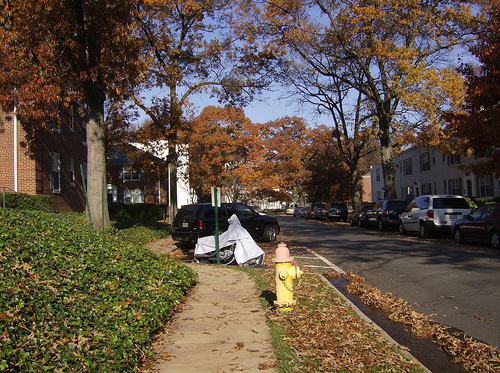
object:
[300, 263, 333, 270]
lines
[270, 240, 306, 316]
hydrant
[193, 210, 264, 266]
motorcycle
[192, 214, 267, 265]
white cloth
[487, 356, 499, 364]
leaves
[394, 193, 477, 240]
minivan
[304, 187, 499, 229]
curb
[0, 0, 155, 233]
tree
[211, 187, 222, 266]
post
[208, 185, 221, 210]
sign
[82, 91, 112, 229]
trunk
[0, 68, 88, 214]
building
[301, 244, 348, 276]
lines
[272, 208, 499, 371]
street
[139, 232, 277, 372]
sidewalk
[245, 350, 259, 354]
leaves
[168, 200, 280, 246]
suv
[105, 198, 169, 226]
shrubs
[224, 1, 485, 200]
tree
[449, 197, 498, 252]
car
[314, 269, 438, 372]
curb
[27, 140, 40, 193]
edge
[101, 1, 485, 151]
sky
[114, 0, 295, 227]
trees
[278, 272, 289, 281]
valve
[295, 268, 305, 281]
valve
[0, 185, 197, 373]
grass